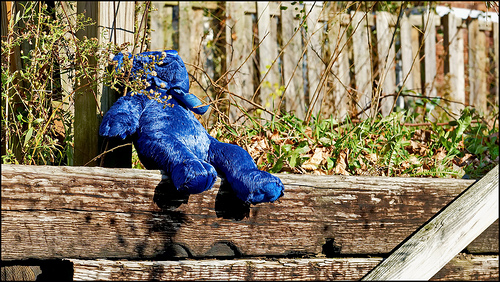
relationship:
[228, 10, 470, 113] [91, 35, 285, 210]
fence has animal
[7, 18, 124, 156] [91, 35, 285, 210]
plant next to bear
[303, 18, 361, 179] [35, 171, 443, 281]
hole in wood